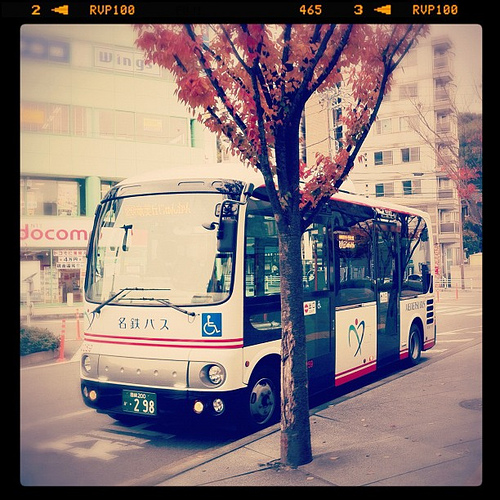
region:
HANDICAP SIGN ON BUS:
[194, 311, 227, 337]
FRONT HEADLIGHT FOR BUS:
[197, 360, 227, 390]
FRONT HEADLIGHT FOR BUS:
[76, 348, 100, 375]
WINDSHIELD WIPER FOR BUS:
[86, 281, 138, 316]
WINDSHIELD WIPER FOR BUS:
[141, 291, 203, 319]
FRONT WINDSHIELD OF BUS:
[85, 192, 245, 307]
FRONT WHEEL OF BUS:
[244, 371, 278, 428]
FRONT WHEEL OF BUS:
[104, 409, 136, 429]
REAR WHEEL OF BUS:
[405, 316, 428, 372]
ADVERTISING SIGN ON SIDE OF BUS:
[334, 309, 381, 381]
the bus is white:
[24, 188, 433, 418]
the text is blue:
[124, 305, 174, 332]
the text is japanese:
[114, 313, 175, 332]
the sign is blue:
[200, 300, 225, 340]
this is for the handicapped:
[197, 303, 224, 343]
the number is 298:
[115, 384, 154, 417]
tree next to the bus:
[267, 120, 308, 454]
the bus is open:
[335, 186, 410, 395]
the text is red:
[25, 215, 100, 257]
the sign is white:
[12, 215, 102, 243]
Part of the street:
[66, 444, 117, 466]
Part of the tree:
[284, 304, 303, 368]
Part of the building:
[46, 149, 79, 161]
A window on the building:
[397, 144, 422, 164]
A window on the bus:
[81, 187, 243, 309]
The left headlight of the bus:
[198, 361, 224, 386]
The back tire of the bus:
[402, 316, 422, 362]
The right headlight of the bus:
[77, 351, 92, 372]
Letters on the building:
[95, 49, 160, 74]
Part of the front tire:
[254, 373, 264, 386]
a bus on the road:
[80, 179, 461, 416]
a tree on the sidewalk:
[243, 143, 345, 468]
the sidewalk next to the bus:
[141, 373, 485, 485]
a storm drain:
[452, 390, 487, 410]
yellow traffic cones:
[49, 313, 71, 364]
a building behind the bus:
[348, 155, 475, 276]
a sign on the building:
[18, 222, 93, 240]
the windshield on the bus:
[92, 196, 225, 308]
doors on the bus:
[303, 220, 338, 388]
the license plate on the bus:
[118, 385, 155, 412]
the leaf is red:
[242, 115, 262, 137]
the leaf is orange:
[361, 62, 496, 87]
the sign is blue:
[201, 312, 218, 335]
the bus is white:
[218, 352, 242, 368]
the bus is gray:
[141, 368, 163, 381]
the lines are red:
[154, 334, 175, 350]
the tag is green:
[126, 390, 148, 410]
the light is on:
[188, 398, 205, 415]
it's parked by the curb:
[336, 375, 383, 399]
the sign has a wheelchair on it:
[201, 313, 220, 340]